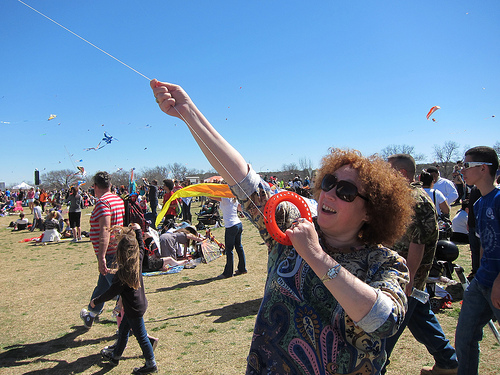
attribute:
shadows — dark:
[0, 272, 262, 373]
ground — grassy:
[0, 202, 498, 373]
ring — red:
[262, 182, 315, 251]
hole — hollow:
[275, 199, 305, 231]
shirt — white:
[89, 187, 131, 262]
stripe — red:
[94, 200, 125, 216]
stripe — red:
[93, 209, 118, 225]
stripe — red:
[106, 217, 118, 224]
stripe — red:
[109, 208, 124, 217]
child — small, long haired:
[100, 224, 167, 374]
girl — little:
[102, 227, 161, 374]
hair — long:
[115, 225, 144, 300]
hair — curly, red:
[485, 148, 487, 153]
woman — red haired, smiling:
[148, 73, 417, 373]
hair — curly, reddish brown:
[301, 144, 418, 255]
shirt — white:
[218, 192, 236, 229]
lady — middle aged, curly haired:
[149, 78, 414, 373]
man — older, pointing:
[78, 169, 126, 329]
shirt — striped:
[88, 191, 125, 255]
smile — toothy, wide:
[293, 185, 376, 245]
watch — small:
[312, 255, 354, 304]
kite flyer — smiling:
[207, 132, 423, 351]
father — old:
[75, 171, 122, 326]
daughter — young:
[99, 220, 164, 372]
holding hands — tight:
[94, 255, 116, 277]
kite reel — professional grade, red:
[265, 170, 326, 264]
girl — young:
[119, 236, 180, 314]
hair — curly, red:
[316, 146, 407, 249]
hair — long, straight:
[114, 231, 144, 293]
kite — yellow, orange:
[151, 167, 242, 227]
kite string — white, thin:
[16, 0, 273, 223]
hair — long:
[118, 236, 141, 293]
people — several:
[5, 183, 245, 269]